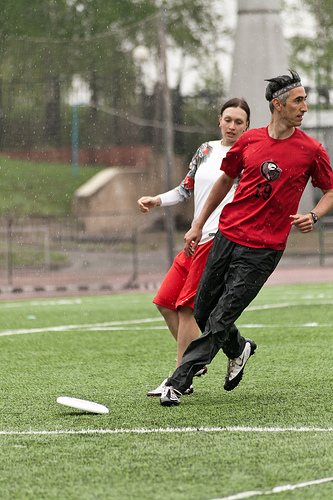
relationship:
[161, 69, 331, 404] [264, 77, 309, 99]
man wearing band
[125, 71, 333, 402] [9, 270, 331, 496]
people running in  a field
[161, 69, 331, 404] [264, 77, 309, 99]
man wearing a band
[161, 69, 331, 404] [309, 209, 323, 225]
man wearing a watch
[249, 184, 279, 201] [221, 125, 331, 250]
number on mans shirt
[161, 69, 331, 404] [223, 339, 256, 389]
man wearing a cleat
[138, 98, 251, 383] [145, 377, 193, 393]
woman wearing a cleat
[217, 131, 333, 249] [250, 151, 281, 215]
shirt has logo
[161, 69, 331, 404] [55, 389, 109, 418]
man playing frisbee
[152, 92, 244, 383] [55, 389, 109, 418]
woman playing frisbee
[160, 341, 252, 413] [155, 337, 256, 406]
shoes on man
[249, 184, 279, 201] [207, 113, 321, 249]
number on shirt